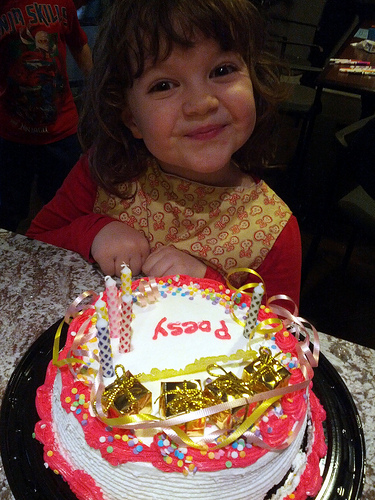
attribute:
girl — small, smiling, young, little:
[25, 5, 300, 313]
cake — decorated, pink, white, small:
[31, 274, 330, 499]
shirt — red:
[1, 3, 88, 147]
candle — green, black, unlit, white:
[242, 275, 266, 340]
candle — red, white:
[119, 290, 134, 350]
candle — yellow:
[116, 261, 132, 299]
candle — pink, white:
[101, 271, 119, 337]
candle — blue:
[95, 316, 113, 378]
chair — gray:
[263, 33, 322, 158]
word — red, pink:
[151, 314, 233, 346]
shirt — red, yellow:
[19, 142, 304, 318]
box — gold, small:
[94, 368, 149, 415]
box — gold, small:
[161, 379, 201, 431]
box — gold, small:
[207, 371, 248, 437]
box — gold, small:
[244, 351, 284, 403]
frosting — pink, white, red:
[32, 275, 329, 497]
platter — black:
[1, 318, 368, 499]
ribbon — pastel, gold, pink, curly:
[263, 293, 327, 371]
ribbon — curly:
[220, 265, 274, 342]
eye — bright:
[146, 77, 182, 95]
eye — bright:
[206, 60, 238, 79]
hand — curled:
[143, 246, 209, 280]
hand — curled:
[86, 218, 149, 281]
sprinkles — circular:
[130, 287, 247, 315]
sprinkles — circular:
[60, 382, 289, 473]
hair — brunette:
[78, 7, 299, 203]